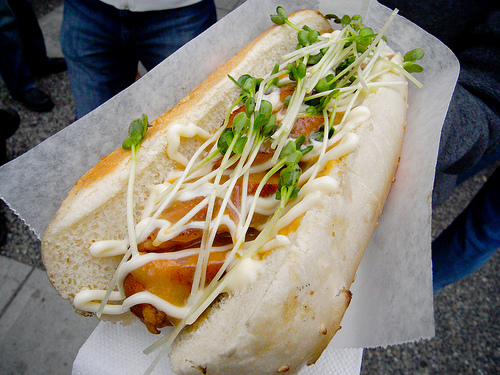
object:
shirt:
[96, 0, 203, 16]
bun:
[37, 8, 334, 326]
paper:
[3, 0, 460, 350]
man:
[0, 0, 60, 142]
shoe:
[8, 88, 55, 117]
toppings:
[303, 105, 371, 162]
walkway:
[0, 0, 497, 374]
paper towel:
[64, 314, 368, 374]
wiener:
[121, 73, 334, 335]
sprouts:
[312, 6, 404, 92]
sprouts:
[133, 107, 251, 374]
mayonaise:
[162, 119, 212, 167]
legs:
[55, 14, 139, 123]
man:
[56, 0, 218, 126]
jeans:
[56, 0, 220, 127]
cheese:
[131, 251, 229, 305]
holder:
[0, 0, 462, 351]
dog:
[120, 37, 370, 335]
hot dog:
[36, 9, 408, 375]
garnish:
[120, 112, 153, 263]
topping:
[221, 255, 266, 295]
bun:
[162, 39, 410, 375]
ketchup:
[226, 103, 245, 129]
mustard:
[295, 174, 341, 202]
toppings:
[316, 30, 344, 43]